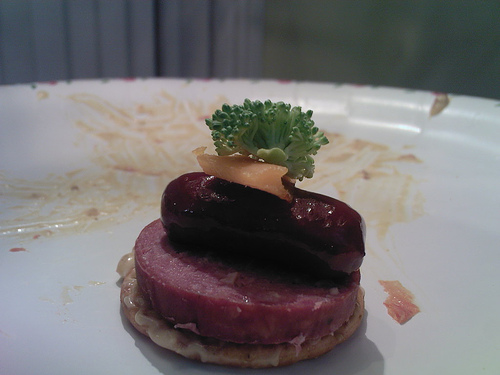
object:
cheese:
[190, 143, 294, 202]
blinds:
[0, 0, 267, 100]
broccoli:
[202, 97, 331, 184]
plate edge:
[0, 75, 499, 108]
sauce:
[375, 277, 417, 325]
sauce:
[0, 93, 429, 244]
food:
[117, 97, 370, 374]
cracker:
[118, 252, 366, 367]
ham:
[158, 171, 365, 278]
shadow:
[119, 313, 385, 373]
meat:
[135, 217, 362, 341]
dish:
[0, 77, 499, 373]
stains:
[5, 68, 206, 271]